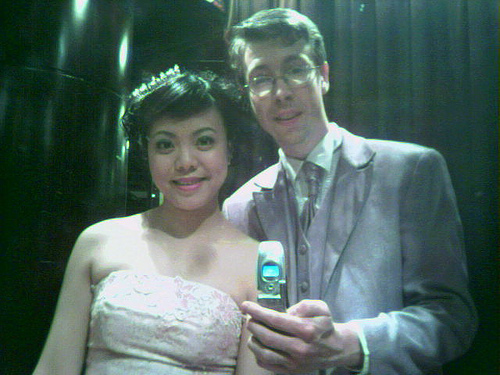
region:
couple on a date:
[37, 29, 441, 374]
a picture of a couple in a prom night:
[111, 3, 427, 363]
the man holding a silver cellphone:
[238, 236, 318, 374]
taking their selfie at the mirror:
[113, 24, 370, 332]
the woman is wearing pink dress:
[108, 101, 248, 373]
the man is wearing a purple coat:
[229, 35, 482, 374]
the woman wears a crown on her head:
[129, 64, 204, 114]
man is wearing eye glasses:
[241, 58, 335, 109]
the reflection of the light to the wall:
[56, 19, 147, 88]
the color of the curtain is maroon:
[339, 14, 475, 120]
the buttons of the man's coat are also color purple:
[289, 234, 314, 301]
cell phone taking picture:
[204, 207, 354, 374]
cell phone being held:
[214, 230, 336, 373]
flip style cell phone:
[246, 232, 347, 373]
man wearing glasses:
[216, 1, 367, 158]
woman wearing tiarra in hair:
[81, 50, 245, 226]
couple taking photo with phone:
[9, 15, 474, 372]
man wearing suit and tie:
[197, 12, 462, 372]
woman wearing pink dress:
[8, 44, 270, 372]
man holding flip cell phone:
[217, 8, 457, 363]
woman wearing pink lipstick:
[55, 35, 250, 301]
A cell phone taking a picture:
[257, 237, 288, 312]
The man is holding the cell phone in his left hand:
[243, 239, 335, 369]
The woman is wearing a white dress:
[86, 269, 239, 374]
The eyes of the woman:
[155, 137, 215, 149]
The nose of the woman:
[177, 148, 196, 172]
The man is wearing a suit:
[221, 122, 476, 374]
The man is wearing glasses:
[245, 62, 324, 96]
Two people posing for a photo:
[31, 11, 474, 374]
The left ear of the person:
[318, 59, 331, 91]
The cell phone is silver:
[258, 242, 290, 309]